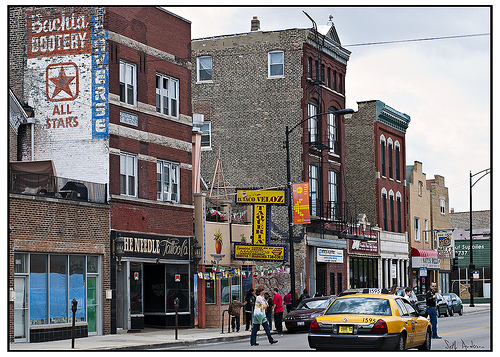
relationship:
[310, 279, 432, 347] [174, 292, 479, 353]
taxicab on street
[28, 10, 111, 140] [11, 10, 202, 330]
sign painted building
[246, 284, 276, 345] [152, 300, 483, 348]
woman walking street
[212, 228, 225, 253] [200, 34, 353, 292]
pineapple painted building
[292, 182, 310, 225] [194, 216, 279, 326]
banner strung restaurant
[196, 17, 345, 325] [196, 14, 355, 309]
brick on building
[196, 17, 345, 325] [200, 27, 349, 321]
brick on building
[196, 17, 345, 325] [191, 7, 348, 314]
brick on building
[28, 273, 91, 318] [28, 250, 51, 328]
tarp on window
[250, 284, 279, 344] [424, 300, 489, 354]
man walking on road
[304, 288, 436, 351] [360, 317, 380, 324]
cab numbered 1595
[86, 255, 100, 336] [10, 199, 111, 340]
window of store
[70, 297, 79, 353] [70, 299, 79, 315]
meter with head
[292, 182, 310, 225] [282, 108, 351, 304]
banner on lamp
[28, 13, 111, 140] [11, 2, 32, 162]
sign on wall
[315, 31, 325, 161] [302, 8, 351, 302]
escape on building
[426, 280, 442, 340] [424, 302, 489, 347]
man standing in street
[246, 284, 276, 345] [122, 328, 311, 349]
woman walking in street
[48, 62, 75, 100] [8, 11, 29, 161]
star on wall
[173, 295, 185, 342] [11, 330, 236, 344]
meter on sidewalk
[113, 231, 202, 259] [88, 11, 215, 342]
sign over a store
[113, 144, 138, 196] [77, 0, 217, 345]
window over a store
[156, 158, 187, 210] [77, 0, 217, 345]
window over a store